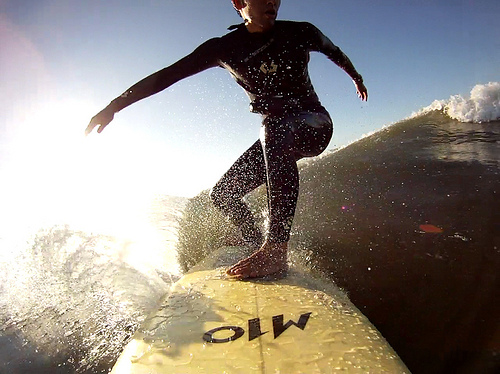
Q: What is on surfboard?
A: MLo.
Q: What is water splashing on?
A: Surfboard.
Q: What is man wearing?
A: Wet suit.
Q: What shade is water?
A: Dark blue.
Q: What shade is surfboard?
A: White.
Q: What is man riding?
A: Wave.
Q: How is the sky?
A: Clear.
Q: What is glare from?
A: Sun.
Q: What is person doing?
A: Surfing.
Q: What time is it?
A: Afternoon.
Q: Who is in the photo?
A: A man.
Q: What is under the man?
A: A board.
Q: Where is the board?
A: In the water.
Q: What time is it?
A: Afternoon.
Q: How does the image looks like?
A: Good.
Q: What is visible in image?
A: Surfer.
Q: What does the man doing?
A: Surfing.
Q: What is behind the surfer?
A: Water.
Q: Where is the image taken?
A: Beach.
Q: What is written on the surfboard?
A: M10.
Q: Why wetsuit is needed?
A: To protect.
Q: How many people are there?
A: One.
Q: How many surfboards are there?
A: One.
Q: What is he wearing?
A: Wetsuit.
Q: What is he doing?
A: Surfing.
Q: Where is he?
A: Ocean.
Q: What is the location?
A: Outside.